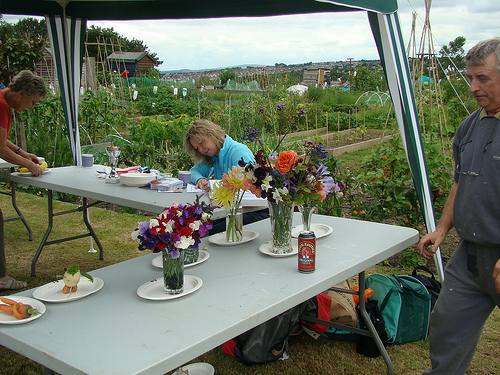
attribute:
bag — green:
[361, 260, 460, 358]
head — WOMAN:
[178, 119, 225, 160]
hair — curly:
[191, 95, 258, 150]